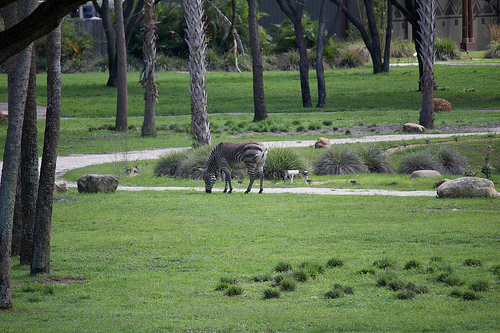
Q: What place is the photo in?
A: It is at the park.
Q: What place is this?
A: It is a park.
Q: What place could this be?
A: It is a park.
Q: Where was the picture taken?
A: It was taken at the park.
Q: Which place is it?
A: It is a park.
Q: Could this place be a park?
A: Yes, it is a park.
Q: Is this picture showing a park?
A: Yes, it is showing a park.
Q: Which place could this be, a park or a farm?
A: It is a park.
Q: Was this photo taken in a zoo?
A: No, the picture was taken in a park.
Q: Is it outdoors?
A: Yes, it is outdoors.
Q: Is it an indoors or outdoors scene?
A: It is outdoors.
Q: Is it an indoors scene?
A: No, it is outdoors.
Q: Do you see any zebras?
A: Yes, there is a zebra.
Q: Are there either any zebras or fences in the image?
A: Yes, there is a zebra.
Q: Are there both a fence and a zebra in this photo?
A: No, there is a zebra but no fences.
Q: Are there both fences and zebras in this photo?
A: No, there is a zebra but no fences.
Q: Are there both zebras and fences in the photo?
A: No, there is a zebra but no fences.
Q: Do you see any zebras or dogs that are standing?
A: Yes, the zebra is standing.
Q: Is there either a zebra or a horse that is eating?
A: Yes, the zebra is eating.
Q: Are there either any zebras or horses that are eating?
A: Yes, the zebra is eating.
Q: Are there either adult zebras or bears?
A: Yes, there is an adult zebra.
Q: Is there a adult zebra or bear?
A: Yes, there is an adult zebra.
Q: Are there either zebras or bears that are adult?
A: Yes, the zebra is adult.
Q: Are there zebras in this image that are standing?
A: Yes, there is a zebra that is standing.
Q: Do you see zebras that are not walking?
A: Yes, there is a zebra that is standing .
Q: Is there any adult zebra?
A: Yes, there is an adult zebra.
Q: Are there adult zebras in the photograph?
A: Yes, there is an adult zebra.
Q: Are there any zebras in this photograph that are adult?
A: Yes, there is a zebra that is adult.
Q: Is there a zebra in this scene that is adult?
A: Yes, there is a zebra that is adult.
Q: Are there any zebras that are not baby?
A: Yes, there is a adult zebra.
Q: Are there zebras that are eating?
A: Yes, there is a zebra that is eating.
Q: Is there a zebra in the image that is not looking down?
A: Yes, there is a zebra that is eating.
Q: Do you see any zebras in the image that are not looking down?
A: Yes, there is a zebra that is eating .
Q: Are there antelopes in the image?
A: No, there are no antelopes.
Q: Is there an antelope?
A: No, there are no antelopes.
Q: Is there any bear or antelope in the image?
A: No, there are no antelopes or bears.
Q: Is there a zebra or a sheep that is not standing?
A: No, there is a zebra but it is standing.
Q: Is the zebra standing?
A: Yes, the zebra is standing.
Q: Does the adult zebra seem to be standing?
A: Yes, the zebra is standing.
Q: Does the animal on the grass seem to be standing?
A: Yes, the zebra is standing.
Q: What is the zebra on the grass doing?
A: The zebra is standing.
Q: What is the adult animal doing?
A: The zebra is standing.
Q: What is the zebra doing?
A: The zebra is standing.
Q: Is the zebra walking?
A: No, the zebra is standing.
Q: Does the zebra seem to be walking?
A: No, the zebra is standing.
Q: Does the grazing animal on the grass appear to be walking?
A: No, the zebra is standing.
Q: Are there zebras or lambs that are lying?
A: No, there is a zebra but it is standing.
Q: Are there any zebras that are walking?
A: No, there is a zebra but it is standing.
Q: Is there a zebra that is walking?
A: No, there is a zebra but it is standing.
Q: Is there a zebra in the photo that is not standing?
A: No, there is a zebra but it is standing.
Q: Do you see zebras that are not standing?
A: No, there is a zebra but it is standing.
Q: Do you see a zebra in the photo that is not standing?
A: No, there is a zebra but it is standing.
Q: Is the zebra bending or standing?
A: The zebra is standing.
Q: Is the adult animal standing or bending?
A: The zebra is standing.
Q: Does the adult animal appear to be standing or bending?
A: The zebra is standing.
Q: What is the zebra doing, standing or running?
A: The zebra is standing.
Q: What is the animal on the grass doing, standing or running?
A: The zebra is standing.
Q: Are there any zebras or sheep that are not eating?
A: No, there is a zebra but it is eating.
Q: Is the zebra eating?
A: Yes, the zebra is eating.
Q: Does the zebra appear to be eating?
A: Yes, the zebra is eating.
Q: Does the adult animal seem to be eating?
A: Yes, the zebra is eating.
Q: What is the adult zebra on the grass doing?
A: The zebra is eating.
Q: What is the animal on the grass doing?
A: The zebra is eating.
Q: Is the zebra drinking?
A: No, the zebra is eating.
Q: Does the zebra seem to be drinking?
A: No, the zebra is eating.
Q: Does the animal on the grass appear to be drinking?
A: No, the zebra is eating.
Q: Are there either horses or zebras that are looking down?
A: No, there is a zebra but it is eating.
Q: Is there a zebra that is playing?
A: No, there is a zebra but it is eating.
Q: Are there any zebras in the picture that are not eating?
A: No, there is a zebra but it is eating.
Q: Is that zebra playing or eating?
A: The zebra is eating.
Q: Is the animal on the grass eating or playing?
A: The zebra is eating.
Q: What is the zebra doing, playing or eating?
A: The zebra is eating.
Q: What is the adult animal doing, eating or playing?
A: The zebra is eating.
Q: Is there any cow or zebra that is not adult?
A: No, there is a zebra but it is adult.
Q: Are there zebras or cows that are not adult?
A: No, there is a zebra but it is adult.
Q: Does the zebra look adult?
A: Yes, the zebra is adult.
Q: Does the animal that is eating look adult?
A: Yes, the zebra is adult.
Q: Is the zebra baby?
A: No, the zebra is adult.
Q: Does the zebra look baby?
A: No, the zebra is adult.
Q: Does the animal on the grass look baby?
A: No, the zebra is adult.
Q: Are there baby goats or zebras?
A: No, there is a zebra but it is adult.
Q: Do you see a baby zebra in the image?
A: No, there is a zebra but it is adult.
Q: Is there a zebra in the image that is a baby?
A: No, there is a zebra but it is adult.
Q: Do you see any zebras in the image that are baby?
A: No, there is a zebra but it is adult.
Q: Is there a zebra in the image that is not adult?
A: No, there is a zebra but it is adult.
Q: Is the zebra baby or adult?
A: The zebra is adult.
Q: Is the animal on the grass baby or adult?
A: The zebra is adult.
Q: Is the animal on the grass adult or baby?
A: The zebra is adult.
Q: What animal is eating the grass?
A: The zebra is eating the grass.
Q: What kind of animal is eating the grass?
A: The animal is a zebra.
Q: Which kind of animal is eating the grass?
A: The animal is a zebra.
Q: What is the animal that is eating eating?
A: The zebra is eating grass.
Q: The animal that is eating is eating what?
A: The zebra is eating grass.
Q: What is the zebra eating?
A: The zebra is eating grass.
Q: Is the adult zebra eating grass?
A: Yes, the zebra is eating grass.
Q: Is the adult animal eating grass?
A: Yes, the zebra is eating grass.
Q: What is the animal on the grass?
A: The animal is a zebra.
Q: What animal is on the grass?
A: The animal is a zebra.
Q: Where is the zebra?
A: The zebra is on the grass.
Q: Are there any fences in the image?
A: No, there are no fences.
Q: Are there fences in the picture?
A: No, there are no fences.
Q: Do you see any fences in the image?
A: No, there are no fences.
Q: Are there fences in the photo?
A: No, there are no fences.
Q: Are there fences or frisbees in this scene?
A: No, there are no fences or frisbees.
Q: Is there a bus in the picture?
A: No, there are no buses.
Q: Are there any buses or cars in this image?
A: No, there are no buses or cars.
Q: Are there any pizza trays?
A: No, there are no pizza trays.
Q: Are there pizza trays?
A: No, there are no pizza trays.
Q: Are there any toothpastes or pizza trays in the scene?
A: No, there are no pizza trays or toothpastes.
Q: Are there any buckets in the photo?
A: No, there are no buckets.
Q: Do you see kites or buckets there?
A: No, there are no buckets or kites.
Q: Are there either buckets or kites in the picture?
A: No, there are no buckets or kites.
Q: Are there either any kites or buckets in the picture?
A: No, there are no buckets or kites.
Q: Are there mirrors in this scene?
A: No, there are no mirrors.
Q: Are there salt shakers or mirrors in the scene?
A: No, there are no mirrors or salt shakers.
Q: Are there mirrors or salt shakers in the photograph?
A: No, there are no mirrors or salt shakers.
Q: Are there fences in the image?
A: No, there are no fences.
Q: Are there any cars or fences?
A: No, there are no fences or cars.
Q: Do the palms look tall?
A: Yes, the palms are tall.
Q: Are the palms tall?
A: Yes, the palms are tall.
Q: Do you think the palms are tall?
A: Yes, the palms are tall.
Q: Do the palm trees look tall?
A: Yes, the palm trees are tall.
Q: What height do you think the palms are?
A: The palms are tall.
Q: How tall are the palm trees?
A: The palm trees are tall.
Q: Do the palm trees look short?
A: No, the palm trees are tall.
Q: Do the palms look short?
A: No, the palms are tall.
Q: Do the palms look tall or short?
A: The palms are tall.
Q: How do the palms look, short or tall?
A: The palms are tall.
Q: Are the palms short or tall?
A: The palms are tall.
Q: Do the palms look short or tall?
A: The palms are tall.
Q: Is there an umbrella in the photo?
A: No, there are no umbrellas.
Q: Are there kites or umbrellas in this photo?
A: No, there are no umbrellas or kites.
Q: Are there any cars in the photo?
A: No, there are no cars.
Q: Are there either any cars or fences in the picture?
A: No, there are no cars or fences.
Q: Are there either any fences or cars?
A: No, there are no cars or fences.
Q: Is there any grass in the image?
A: Yes, there is grass.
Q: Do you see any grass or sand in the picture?
A: Yes, there is grass.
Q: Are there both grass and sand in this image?
A: No, there is grass but no sand.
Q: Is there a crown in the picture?
A: No, there are no crowns.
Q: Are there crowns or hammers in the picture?
A: No, there are no crowns or hammers.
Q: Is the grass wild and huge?
A: Yes, the grass is wild and huge.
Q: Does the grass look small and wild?
A: No, the grass is wild but huge.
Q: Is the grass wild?
A: Yes, the grass is wild.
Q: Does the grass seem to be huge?
A: Yes, the grass is huge.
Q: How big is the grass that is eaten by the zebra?
A: The grass is huge.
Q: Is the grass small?
A: No, the grass is huge.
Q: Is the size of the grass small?
A: No, the grass is huge.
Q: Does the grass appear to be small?
A: No, the grass is huge.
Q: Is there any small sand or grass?
A: No, there is grass but it is huge.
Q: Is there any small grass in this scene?
A: No, there is grass but it is huge.